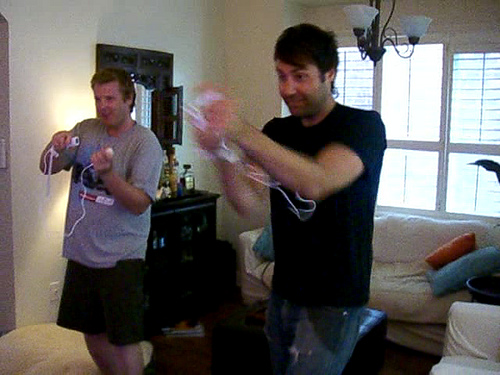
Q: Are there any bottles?
A: Yes, there is a bottle.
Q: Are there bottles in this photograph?
A: Yes, there is a bottle.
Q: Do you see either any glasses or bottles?
A: Yes, there is a bottle.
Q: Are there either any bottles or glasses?
A: Yes, there is a bottle.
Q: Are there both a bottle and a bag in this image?
A: No, there is a bottle but no bags.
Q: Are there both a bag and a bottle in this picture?
A: No, there is a bottle but no bags.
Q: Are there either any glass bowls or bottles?
A: Yes, there is a glass bottle.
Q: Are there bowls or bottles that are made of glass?
A: Yes, the bottle is made of glass.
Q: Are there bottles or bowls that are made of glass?
A: Yes, the bottle is made of glass.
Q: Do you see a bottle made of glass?
A: Yes, there is a bottle that is made of glass.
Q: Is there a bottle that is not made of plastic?
A: Yes, there is a bottle that is made of glass.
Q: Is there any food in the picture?
A: No, there is no food.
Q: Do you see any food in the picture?
A: No, there is no food.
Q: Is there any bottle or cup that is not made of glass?
A: No, there is a bottle but it is made of glass.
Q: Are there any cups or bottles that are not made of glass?
A: No, there is a bottle but it is made of glass.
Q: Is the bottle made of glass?
A: Yes, the bottle is made of glass.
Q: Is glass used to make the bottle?
A: Yes, the bottle is made of glass.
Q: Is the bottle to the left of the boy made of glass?
A: Yes, the bottle is made of glass.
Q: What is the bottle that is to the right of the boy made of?
A: The bottle is made of glass.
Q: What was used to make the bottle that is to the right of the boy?
A: The bottle is made of glass.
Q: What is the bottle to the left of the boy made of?
A: The bottle is made of glass.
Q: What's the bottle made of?
A: The bottle is made of glass.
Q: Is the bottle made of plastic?
A: No, the bottle is made of glass.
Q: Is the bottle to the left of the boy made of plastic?
A: No, the bottle is made of glass.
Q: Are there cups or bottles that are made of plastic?
A: No, there is a bottle but it is made of glass.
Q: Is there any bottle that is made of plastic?
A: No, there is a bottle but it is made of glass.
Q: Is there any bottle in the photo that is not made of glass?
A: No, there is a bottle but it is made of glass.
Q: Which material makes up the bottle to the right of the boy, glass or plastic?
A: The bottle is made of glass.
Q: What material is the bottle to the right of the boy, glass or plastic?
A: The bottle is made of glass.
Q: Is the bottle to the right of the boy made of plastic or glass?
A: The bottle is made of glass.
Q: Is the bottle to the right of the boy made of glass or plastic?
A: The bottle is made of glass.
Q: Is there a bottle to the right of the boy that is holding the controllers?
A: Yes, there is a bottle to the right of the boy.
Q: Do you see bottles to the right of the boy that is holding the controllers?
A: Yes, there is a bottle to the right of the boy.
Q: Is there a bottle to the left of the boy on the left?
A: No, the bottle is to the right of the boy.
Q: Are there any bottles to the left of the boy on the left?
A: No, the bottle is to the right of the boy.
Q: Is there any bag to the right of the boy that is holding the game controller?
A: No, there is a bottle to the right of the boy.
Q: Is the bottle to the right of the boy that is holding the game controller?
A: Yes, the bottle is to the right of the boy.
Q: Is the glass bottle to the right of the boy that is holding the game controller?
A: Yes, the bottle is to the right of the boy.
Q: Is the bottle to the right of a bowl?
A: No, the bottle is to the right of the boy.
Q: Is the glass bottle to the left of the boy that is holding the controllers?
A: No, the bottle is to the right of the boy.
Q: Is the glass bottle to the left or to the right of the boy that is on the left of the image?
A: The bottle is to the right of the boy.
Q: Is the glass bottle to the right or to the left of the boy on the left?
A: The bottle is to the right of the boy.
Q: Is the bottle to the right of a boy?
A: No, the bottle is to the left of a boy.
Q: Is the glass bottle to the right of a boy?
A: No, the bottle is to the left of a boy.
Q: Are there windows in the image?
A: Yes, there is a window.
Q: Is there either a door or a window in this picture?
A: Yes, there is a window.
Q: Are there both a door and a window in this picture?
A: No, there is a window but no doors.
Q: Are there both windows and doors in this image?
A: No, there is a window but no doors.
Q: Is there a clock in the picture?
A: No, there are no clocks.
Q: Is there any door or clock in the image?
A: No, there are no clocks or doors.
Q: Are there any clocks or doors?
A: No, there are no clocks or doors.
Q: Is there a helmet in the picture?
A: No, there are no helmets.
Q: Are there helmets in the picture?
A: No, there are no helmets.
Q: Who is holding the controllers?
A: The boy is holding the controllers.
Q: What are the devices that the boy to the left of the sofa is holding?
A: The devices are controllers.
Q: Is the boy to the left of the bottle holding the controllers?
A: Yes, the boy is holding the controllers.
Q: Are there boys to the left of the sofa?
A: Yes, there is a boy to the left of the sofa.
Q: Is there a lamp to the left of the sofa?
A: No, there is a boy to the left of the sofa.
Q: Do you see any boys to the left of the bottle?
A: Yes, there is a boy to the left of the bottle.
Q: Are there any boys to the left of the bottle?
A: Yes, there is a boy to the left of the bottle.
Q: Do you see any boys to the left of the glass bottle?
A: Yes, there is a boy to the left of the bottle.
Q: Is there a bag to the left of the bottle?
A: No, there is a boy to the left of the bottle.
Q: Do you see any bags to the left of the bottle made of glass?
A: No, there is a boy to the left of the bottle.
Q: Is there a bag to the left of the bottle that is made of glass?
A: No, there is a boy to the left of the bottle.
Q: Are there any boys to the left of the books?
A: Yes, there is a boy to the left of the books.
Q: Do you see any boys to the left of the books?
A: Yes, there is a boy to the left of the books.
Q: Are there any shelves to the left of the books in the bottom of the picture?
A: No, there is a boy to the left of the books.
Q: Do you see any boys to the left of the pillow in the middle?
A: Yes, there is a boy to the left of the pillow.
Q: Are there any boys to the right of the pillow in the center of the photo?
A: No, the boy is to the left of the pillow.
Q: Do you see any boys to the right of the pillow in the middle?
A: No, the boy is to the left of the pillow.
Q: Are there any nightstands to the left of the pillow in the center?
A: No, there is a boy to the left of the pillow.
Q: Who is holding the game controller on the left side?
A: The boy is holding the game controller.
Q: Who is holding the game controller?
A: The boy is holding the game controller.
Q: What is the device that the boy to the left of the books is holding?
A: The device is a game controller.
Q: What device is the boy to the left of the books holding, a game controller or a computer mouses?
A: The boy is holding a game controller.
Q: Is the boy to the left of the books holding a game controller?
A: Yes, the boy is holding a game controller.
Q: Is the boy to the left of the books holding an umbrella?
A: No, the boy is holding a game controller.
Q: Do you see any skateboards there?
A: No, there are no skateboards.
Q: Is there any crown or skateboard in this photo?
A: No, there are no skateboards or crowns.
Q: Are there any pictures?
A: No, there are no pictures.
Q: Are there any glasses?
A: No, there are no glasses.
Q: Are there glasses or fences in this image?
A: No, there are no glasses or fences.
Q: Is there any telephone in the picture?
A: No, there are no phones.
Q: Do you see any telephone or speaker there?
A: No, there are no phones or speakers.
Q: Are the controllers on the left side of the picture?
A: Yes, the controllers are on the left of the image.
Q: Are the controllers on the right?
A: No, the controllers are on the left of the image.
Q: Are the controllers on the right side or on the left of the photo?
A: The controllers are on the left of the image.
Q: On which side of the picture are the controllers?
A: The controllers are on the left of the image.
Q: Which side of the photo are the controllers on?
A: The controllers are on the left of the image.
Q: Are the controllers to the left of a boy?
A: Yes, the controllers are to the left of a boy.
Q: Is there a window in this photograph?
A: Yes, there is a window.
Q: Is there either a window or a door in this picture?
A: Yes, there is a window.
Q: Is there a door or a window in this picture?
A: Yes, there is a window.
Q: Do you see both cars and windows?
A: No, there is a window but no cars.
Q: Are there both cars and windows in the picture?
A: No, there is a window but no cars.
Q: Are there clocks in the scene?
A: No, there are no clocks.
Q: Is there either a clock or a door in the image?
A: No, there are no clocks or doors.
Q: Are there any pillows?
A: Yes, there is a pillow.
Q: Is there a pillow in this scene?
A: Yes, there is a pillow.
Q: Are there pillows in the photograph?
A: Yes, there is a pillow.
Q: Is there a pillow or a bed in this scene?
A: Yes, there is a pillow.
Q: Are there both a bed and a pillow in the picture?
A: No, there is a pillow but no beds.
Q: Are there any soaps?
A: No, there are no soaps.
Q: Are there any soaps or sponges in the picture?
A: No, there are no soaps or sponges.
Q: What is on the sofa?
A: The pillow is on the sofa.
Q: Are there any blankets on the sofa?
A: No, there is a pillow on the sofa.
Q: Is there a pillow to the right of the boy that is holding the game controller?
A: Yes, there is a pillow to the right of the boy.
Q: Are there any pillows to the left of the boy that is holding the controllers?
A: No, the pillow is to the right of the boy.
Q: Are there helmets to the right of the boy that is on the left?
A: No, there is a pillow to the right of the boy.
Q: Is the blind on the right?
A: Yes, the blind is on the right of the image.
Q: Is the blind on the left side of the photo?
A: No, the blind is on the right of the image.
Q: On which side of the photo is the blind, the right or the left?
A: The blind is on the right of the image.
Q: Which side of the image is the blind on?
A: The blind is on the right of the image.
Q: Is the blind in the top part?
A: Yes, the blind is in the top of the image.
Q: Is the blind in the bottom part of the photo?
A: No, the blind is in the top of the image.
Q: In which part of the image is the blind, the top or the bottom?
A: The blind is in the top of the image.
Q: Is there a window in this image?
A: Yes, there is a window.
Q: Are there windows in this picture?
A: Yes, there is a window.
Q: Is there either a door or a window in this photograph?
A: Yes, there is a window.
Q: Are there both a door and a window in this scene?
A: No, there is a window but no doors.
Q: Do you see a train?
A: No, there are no trains.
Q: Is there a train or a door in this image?
A: No, there are no trains or doors.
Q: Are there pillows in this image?
A: Yes, there is a pillow.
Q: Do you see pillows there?
A: Yes, there is a pillow.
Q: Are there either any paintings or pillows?
A: Yes, there is a pillow.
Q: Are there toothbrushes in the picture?
A: No, there are no toothbrushes.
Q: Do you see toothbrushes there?
A: No, there are no toothbrushes.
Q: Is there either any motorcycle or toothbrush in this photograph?
A: No, there are no toothbrushes or motorcycles.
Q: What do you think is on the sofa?
A: The pillow is on the sofa.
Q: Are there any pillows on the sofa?
A: Yes, there is a pillow on the sofa.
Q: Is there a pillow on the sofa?
A: Yes, there is a pillow on the sofa.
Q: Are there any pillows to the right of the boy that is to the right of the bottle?
A: Yes, there is a pillow to the right of the boy.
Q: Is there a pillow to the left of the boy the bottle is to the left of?
A: No, the pillow is to the right of the boy.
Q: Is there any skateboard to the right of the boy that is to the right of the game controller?
A: No, there is a pillow to the right of the boy.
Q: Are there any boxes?
A: No, there are no boxes.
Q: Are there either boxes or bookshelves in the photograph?
A: No, there are no boxes or bookshelves.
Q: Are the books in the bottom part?
A: Yes, the books are in the bottom of the image.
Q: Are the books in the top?
A: No, the books are in the bottom of the image.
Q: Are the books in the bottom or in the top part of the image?
A: The books are in the bottom of the image.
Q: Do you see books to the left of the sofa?
A: Yes, there are books to the left of the sofa.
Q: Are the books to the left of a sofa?
A: Yes, the books are to the left of a sofa.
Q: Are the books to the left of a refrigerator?
A: No, the books are to the left of a sofa.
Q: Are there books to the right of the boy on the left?
A: Yes, there are books to the right of the boy.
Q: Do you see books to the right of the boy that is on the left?
A: Yes, there are books to the right of the boy.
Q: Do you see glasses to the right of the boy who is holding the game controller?
A: No, there are books to the right of the boy.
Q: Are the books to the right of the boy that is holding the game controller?
A: Yes, the books are to the right of the boy.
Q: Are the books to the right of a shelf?
A: No, the books are to the right of the boy.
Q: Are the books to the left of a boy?
A: Yes, the books are to the left of a boy.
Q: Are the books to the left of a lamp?
A: No, the books are to the left of a boy.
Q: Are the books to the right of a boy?
A: No, the books are to the left of a boy.